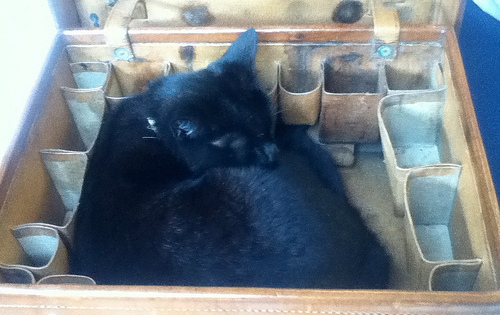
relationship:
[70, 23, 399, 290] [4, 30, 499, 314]
cat laying in container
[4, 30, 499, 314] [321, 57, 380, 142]
container has divider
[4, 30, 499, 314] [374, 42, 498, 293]
container has row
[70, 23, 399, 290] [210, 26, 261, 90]
cat has ear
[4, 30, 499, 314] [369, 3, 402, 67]
container has latch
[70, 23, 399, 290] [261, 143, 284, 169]
cat has nose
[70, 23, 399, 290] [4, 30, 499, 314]
cat inside of container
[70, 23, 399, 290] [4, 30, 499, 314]
cat sleeping in container